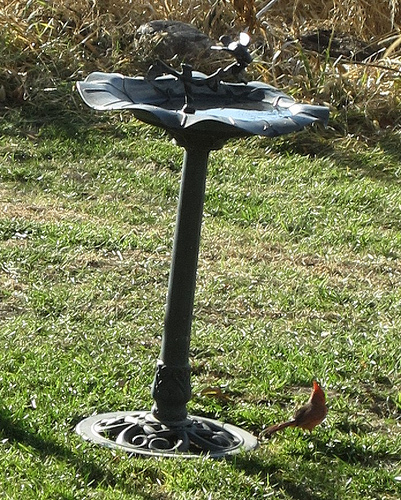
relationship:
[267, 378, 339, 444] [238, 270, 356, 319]
bird on ground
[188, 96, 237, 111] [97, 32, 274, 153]
water in fountain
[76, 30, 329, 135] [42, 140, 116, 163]
bath on grass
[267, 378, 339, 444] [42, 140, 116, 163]
bird on grass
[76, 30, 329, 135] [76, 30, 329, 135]
bath for bath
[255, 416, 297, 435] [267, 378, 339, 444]
tail attached to bird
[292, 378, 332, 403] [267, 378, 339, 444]
head of bird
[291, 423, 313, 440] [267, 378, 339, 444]
legs of bird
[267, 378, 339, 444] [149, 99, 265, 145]
bird in bath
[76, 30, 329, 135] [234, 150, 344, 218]
bath in yard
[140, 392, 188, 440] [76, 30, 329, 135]
base attached to bath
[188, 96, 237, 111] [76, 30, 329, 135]
water in bath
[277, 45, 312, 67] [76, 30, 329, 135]
weeds are behind bath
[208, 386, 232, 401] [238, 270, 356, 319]
leaf on ground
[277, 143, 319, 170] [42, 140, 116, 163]
shadow on grass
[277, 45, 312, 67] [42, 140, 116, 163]
weeds are in grass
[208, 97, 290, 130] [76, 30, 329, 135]
light on bath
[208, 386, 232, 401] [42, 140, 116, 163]
leaf in grass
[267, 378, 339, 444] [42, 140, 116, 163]
bird on top of grass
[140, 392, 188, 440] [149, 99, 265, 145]
base of bath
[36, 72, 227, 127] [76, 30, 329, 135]
bowl in bath